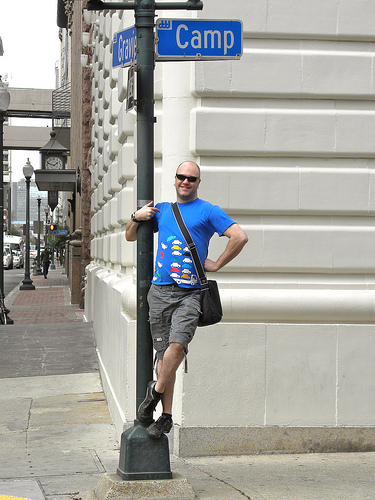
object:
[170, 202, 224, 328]
bag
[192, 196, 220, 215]
shoulder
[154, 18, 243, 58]
sign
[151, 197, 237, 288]
t-shirt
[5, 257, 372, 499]
sidewalk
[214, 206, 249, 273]
arm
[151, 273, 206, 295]
waist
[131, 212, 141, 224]
watch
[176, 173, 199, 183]
sunglasses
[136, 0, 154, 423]
pole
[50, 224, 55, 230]
light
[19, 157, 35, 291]
light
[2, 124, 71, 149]
walkways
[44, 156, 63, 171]
clock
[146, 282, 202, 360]
shorts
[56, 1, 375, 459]
building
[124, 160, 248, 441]
man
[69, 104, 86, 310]
wall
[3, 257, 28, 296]
street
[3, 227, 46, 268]
traffic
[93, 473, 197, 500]
podium